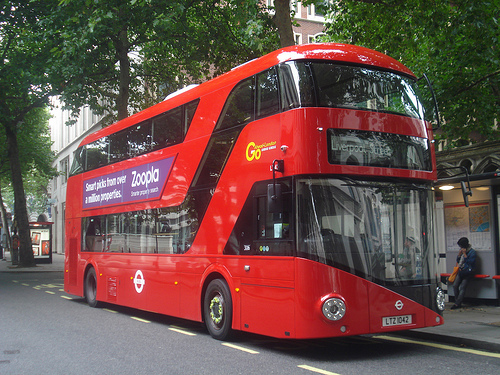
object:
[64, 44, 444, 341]
bus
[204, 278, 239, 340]
tire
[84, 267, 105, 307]
tire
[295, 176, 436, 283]
windshield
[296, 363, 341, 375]
line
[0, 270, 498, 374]
street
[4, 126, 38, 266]
trunk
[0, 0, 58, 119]
leaves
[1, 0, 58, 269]
tree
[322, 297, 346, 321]
headlight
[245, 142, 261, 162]
go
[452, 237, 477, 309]
person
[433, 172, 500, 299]
bus stop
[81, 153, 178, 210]
sign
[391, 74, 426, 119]
reflection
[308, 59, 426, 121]
window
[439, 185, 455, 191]
light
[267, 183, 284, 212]
mirror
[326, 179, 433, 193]
wiper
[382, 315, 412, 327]
plate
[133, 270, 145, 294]
brand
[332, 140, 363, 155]
name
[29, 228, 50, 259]
banner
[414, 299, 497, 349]
walkway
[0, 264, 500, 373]
foreground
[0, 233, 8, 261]
person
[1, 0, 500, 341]
background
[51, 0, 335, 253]
building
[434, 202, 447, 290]
mirror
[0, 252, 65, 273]
walkway